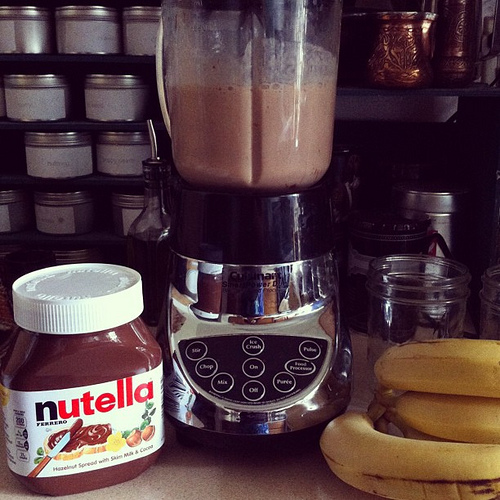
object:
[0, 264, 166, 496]
jar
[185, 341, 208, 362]
button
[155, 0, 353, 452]
blender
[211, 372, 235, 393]
button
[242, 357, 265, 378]
button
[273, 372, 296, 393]
button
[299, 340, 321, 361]
button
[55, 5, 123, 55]
container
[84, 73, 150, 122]
container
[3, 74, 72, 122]
container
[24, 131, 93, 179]
container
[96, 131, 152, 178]
container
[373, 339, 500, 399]
banana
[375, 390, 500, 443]
banana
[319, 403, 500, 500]
banana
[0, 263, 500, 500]
counter